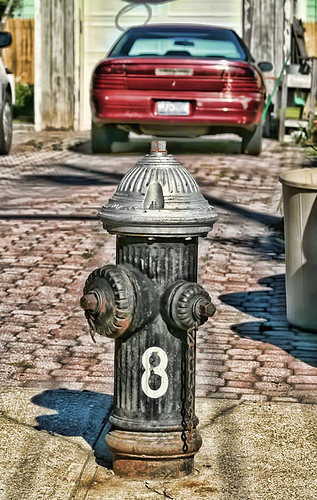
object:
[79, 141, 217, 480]
hydrant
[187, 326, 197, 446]
chain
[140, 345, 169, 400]
8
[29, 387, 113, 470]
shadow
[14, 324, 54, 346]
bricks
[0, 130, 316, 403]
ground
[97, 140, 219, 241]
dome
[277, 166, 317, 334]
trash can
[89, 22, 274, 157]
car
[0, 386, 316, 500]
sidewalk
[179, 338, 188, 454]
shadow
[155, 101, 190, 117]
license plate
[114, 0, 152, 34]
shadow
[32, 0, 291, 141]
garage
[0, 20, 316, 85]
fence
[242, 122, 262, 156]
wheel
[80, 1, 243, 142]
door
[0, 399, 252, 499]
crack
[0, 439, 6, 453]
stains